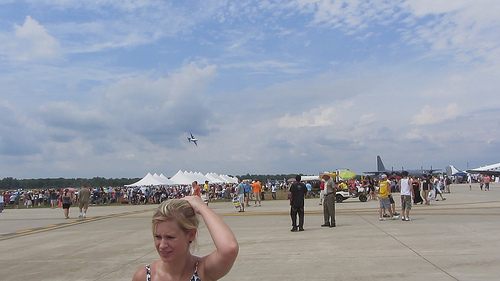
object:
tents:
[127, 168, 243, 188]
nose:
[157, 235, 180, 252]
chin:
[157, 250, 182, 260]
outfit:
[75, 181, 94, 220]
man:
[289, 173, 307, 232]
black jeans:
[291, 205, 304, 227]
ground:
[403, 136, 447, 173]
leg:
[288, 206, 298, 232]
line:
[454, 208, 478, 218]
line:
[458, 198, 475, 208]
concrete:
[423, 220, 497, 235]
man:
[319, 173, 339, 226]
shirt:
[400, 177, 415, 198]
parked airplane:
[363, 154, 441, 182]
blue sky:
[184, 129, 201, 149]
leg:
[329, 205, 336, 229]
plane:
[447, 163, 500, 181]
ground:
[2, 182, 499, 279]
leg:
[402, 203, 415, 223]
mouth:
[156, 247, 176, 257]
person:
[134, 197, 240, 281]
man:
[397, 171, 419, 220]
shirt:
[142, 259, 203, 281]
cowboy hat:
[319, 172, 334, 182]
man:
[376, 175, 395, 218]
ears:
[187, 220, 195, 242]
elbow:
[218, 234, 243, 254]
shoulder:
[132, 257, 158, 276]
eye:
[163, 234, 176, 240]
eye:
[153, 231, 163, 241]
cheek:
[169, 233, 190, 256]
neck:
[155, 246, 193, 268]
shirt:
[289, 181, 308, 223]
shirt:
[252, 179, 266, 199]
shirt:
[377, 180, 390, 197]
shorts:
[374, 195, 394, 208]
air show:
[1, 0, 500, 281]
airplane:
[184, 130, 202, 149]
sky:
[1, 0, 500, 179]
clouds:
[117, 59, 220, 133]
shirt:
[373, 177, 393, 197]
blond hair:
[151, 199, 202, 240]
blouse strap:
[144, 262, 152, 279]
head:
[151, 196, 197, 263]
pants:
[289, 200, 309, 230]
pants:
[322, 192, 338, 223]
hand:
[180, 193, 210, 214]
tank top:
[399, 175, 411, 196]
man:
[79, 182, 91, 218]